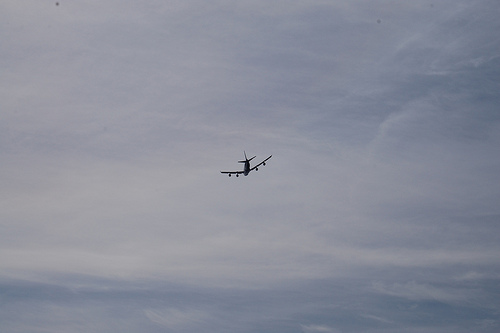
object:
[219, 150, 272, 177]
plane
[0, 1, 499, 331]
sky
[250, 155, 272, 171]
wing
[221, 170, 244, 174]
wing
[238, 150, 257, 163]
tail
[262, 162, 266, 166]
engine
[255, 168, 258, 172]
engine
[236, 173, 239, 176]
engine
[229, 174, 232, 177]
engine